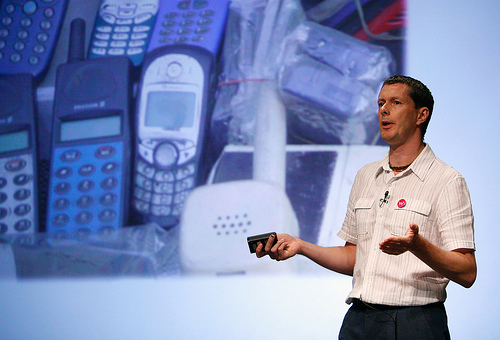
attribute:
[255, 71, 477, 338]
man — black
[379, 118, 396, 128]
mouth — open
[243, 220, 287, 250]
remote — black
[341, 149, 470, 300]
shirt — stripped